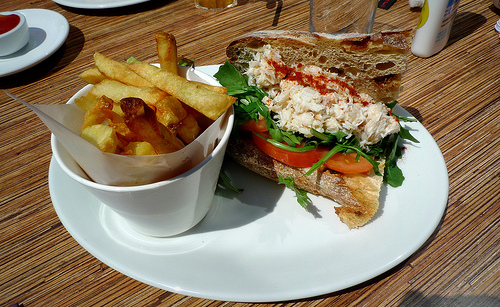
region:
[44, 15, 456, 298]
French fries and sandwitch on a white plate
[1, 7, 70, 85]
Ketchup in a round bowl on a white plate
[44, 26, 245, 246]
French fries wrapped in white paper in a bowl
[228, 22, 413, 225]
Half a sandwitch with lettuce, tomatoes and white meat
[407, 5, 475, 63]
White bottle with yellow label and blue writting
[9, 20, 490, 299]
White plate and food sitting on a wood grain table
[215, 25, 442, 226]
Sandwitch on crusty brown bread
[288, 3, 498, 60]
Clear glass and white bottle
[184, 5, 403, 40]
Shadow of a straw and part of two glasses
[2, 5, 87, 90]
Small bowl and plate casting reflection on table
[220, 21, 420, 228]
a sandwich on the plate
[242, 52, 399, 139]
filling on the sandwich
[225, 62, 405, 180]
lettuce on the sandwich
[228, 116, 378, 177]
tomatoes on the sandwich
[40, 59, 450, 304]
the plate is white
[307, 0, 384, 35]
a glass behind the sandwich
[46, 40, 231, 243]
chips in a cup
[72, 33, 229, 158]
the chips are fried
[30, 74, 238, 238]
the cup is white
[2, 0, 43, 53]
ketchup in a dish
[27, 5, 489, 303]
Lunch on a plate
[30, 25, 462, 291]
A sandwich and fries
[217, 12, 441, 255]
Chicken salad sandwich on a plate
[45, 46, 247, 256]
french fries in a dish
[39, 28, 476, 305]
Food on a round plate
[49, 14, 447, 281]
a plate on a wooden table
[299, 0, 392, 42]
A glass on a table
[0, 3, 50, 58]
A side of ketchup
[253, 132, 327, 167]
Tomato on a sandwich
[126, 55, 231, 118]
A french fry in a pile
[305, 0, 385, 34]
empty clear water glass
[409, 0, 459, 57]
side edge of white bottle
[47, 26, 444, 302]
food on white plate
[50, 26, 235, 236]
french fries in white cup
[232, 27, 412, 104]
bread on top of sandwich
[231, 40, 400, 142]
white meat in sandwich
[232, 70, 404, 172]
vegetable greens under meat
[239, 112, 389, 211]
tomato slices on bread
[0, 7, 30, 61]
ketchup in white cup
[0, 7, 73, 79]
cup on white saucer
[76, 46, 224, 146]
french fries in paper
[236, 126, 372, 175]
tomatoes on sandwich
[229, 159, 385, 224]
bottom piece of bread on sandwich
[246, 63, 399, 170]
filling of sandwich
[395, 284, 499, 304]
shadow shown in bottom right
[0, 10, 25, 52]
cup of ketchup at top left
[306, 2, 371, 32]
part of a drinking glass directly behind sandwich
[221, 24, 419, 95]
top piece of bread on sandwich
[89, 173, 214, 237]
front of cup holding the french fries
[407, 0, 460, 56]
a bottle of something on the table